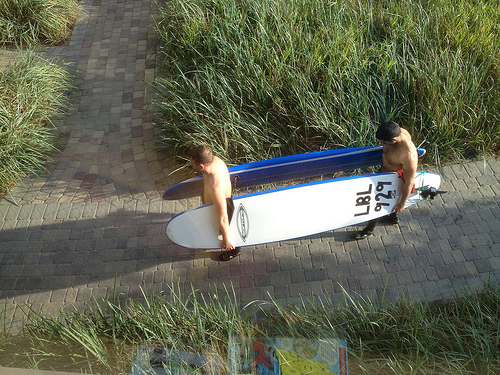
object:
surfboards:
[161, 147, 425, 202]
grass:
[137, 0, 499, 180]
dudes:
[188, 144, 242, 261]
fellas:
[354, 119, 418, 240]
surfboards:
[165, 172, 441, 250]